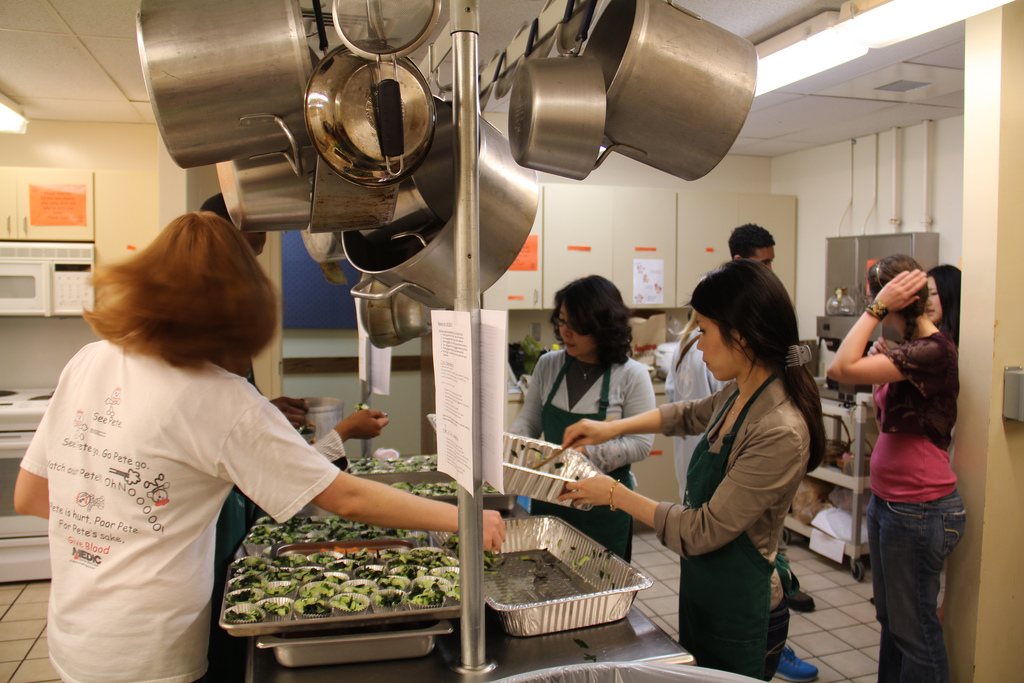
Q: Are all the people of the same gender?
A: Yes, all the people are female.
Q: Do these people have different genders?
A: No, all the people are female.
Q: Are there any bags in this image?
A: No, there are no bags.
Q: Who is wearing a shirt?
A: The girl is wearing a shirt.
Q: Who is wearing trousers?
A: The girl is wearing trousers.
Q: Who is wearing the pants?
A: The girl is wearing trousers.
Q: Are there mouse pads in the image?
A: No, there are no mouse pads.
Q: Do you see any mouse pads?
A: No, there are no mouse pads.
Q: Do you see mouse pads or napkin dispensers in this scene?
A: No, there are no mouse pads or napkin dispensers.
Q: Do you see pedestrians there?
A: No, there are no pedestrians.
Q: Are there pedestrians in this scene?
A: No, there are no pedestrians.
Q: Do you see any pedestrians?
A: No, there are no pedestrians.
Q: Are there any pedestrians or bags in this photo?
A: No, there are no pedestrians or bags.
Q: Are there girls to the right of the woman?
A: Yes, there is a girl to the right of the woman.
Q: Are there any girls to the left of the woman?
A: No, the girl is to the right of the woman.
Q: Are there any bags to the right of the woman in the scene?
A: No, there is a girl to the right of the woman.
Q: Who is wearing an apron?
A: The girl is wearing an apron.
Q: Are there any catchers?
A: No, there are no catchers.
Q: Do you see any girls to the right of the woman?
A: Yes, there is a girl to the right of the woman.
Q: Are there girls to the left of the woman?
A: No, the girl is to the right of the woman.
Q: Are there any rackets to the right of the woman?
A: No, there is a girl to the right of the woman.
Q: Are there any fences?
A: No, there are no fences.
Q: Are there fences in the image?
A: No, there are no fences.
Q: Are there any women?
A: Yes, there is a woman.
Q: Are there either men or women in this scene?
A: Yes, there is a woman.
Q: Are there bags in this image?
A: No, there are no bags.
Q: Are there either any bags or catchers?
A: No, there are no bags or catchers.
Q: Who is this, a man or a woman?
A: This is a woman.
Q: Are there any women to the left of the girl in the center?
A: Yes, there is a woman to the left of the girl.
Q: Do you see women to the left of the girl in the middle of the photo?
A: Yes, there is a woman to the left of the girl.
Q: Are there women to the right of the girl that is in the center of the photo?
A: No, the woman is to the left of the girl.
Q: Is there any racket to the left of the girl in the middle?
A: No, there is a woman to the left of the girl.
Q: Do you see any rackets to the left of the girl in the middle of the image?
A: No, there is a woman to the left of the girl.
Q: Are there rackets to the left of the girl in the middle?
A: No, there is a woman to the left of the girl.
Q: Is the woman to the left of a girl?
A: Yes, the woman is to the left of a girl.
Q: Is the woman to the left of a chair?
A: No, the woman is to the left of a girl.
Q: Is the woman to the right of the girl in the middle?
A: No, the woman is to the left of the girl.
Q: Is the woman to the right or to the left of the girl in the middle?
A: The woman is to the left of the girl.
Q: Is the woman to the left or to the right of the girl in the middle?
A: The woman is to the left of the girl.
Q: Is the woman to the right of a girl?
A: No, the woman is to the left of a girl.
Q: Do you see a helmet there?
A: No, there are no helmets.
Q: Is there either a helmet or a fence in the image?
A: No, there are no helmets or fences.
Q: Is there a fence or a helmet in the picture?
A: No, there are no helmets or fences.